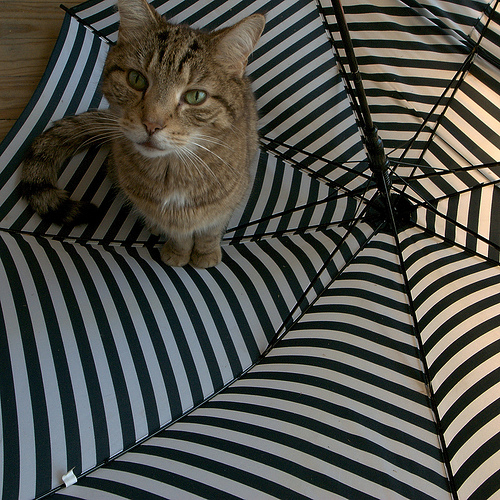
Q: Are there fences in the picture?
A: No, there are no fences.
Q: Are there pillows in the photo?
A: No, there are no pillows.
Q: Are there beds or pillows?
A: No, there are no pillows or beds.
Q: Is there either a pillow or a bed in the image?
A: No, there are no pillows or beds.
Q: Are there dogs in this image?
A: No, there are no dogs.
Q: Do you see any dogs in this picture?
A: No, there are no dogs.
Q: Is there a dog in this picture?
A: No, there are no dogs.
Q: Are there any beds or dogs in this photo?
A: No, there are no dogs or beds.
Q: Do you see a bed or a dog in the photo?
A: No, there are no dogs or beds.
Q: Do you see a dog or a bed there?
A: No, there are no dogs or beds.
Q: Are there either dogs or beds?
A: No, there are no dogs or beds.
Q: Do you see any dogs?
A: No, there are no dogs.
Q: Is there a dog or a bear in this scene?
A: No, there are no dogs or bears.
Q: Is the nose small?
A: Yes, the nose is small.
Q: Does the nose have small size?
A: Yes, the nose is small.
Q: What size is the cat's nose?
A: The nose is small.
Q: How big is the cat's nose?
A: The nose is small.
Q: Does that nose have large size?
A: No, the nose is small.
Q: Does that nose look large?
A: No, the nose is small.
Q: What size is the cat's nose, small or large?
A: The nose is small.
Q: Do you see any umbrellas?
A: Yes, there is an umbrella.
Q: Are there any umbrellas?
A: Yes, there is an umbrella.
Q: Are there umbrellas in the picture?
A: Yes, there is an umbrella.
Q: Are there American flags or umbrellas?
A: Yes, there is an umbrella.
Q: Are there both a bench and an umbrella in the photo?
A: No, there is an umbrella but no benches.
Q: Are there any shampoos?
A: No, there are no shampoos.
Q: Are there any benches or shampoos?
A: No, there are no shampoos or benches.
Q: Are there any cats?
A: Yes, there is a cat.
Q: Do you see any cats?
A: Yes, there is a cat.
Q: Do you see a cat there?
A: Yes, there is a cat.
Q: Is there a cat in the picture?
A: Yes, there is a cat.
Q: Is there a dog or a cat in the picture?
A: Yes, there is a cat.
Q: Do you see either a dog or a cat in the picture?
A: Yes, there is a cat.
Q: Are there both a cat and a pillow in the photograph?
A: No, there is a cat but no pillows.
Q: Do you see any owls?
A: No, there are no owls.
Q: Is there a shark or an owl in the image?
A: No, there are no owls or sharks.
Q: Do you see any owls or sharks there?
A: No, there are no owls or sharks.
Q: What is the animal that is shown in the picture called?
A: The animal is a cat.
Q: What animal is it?
A: The animal is a cat.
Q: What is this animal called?
A: This is a cat.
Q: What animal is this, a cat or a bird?
A: This is a cat.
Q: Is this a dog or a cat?
A: This is a cat.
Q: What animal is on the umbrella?
A: The cat is on the umbrella.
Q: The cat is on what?
A: The cat is on the umbrella.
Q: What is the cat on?
A: The cat is on the umbrella.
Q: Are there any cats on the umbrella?
A: Yes, there is a cat on the umbrella.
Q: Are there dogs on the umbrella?
A: No, there is a cat on the umbrella.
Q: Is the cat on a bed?
A: No, the cat is on the umbrella.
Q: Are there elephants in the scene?
A: No, there are no elephants.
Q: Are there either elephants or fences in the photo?
A: No, there are no elephants or fences.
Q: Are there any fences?
A: No, there are no fences.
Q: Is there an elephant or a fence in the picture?
A: No, there are no fences or elephants.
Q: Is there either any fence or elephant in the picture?
A: No, there are no fences or elephants.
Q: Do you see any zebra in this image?
A: No, there are no zebras.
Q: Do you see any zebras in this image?
A: No, there are no zebras.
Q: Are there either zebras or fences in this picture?
A: No, there are no zebras or fences.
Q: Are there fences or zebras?
A: No, there are no zebras or fences.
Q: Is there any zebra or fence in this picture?
A: No, there are no zebras or fences.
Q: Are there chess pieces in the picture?
A: No, there are no chess pieces.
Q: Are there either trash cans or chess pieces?
A: No, there are no chess pieces or trash cans.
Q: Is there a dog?
A: No, there are no dogs.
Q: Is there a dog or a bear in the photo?
A: No, there are no dogs or bears.